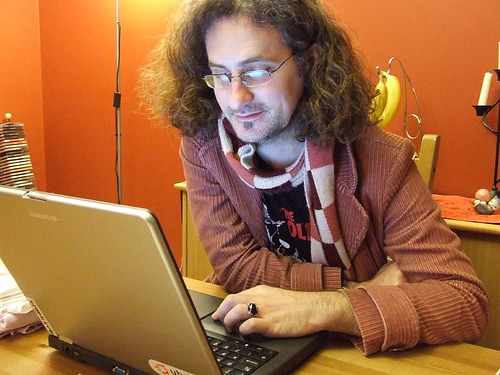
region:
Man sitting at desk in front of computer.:
[136, 1, 489, 356]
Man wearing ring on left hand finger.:
[243, 294, 265, 319]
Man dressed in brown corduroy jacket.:
[176, 119, 491, 360]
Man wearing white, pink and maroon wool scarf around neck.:
[218, 115, 355, 280]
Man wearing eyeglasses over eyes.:
[193, 50, 298, 92]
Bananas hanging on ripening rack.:
[367, 53, 429, 140]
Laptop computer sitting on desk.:
[1, 181, 321, 371]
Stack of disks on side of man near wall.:
[0, 112, 38, 188]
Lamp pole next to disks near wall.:
[100, 0, 130, 200]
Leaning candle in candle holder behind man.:
[469, 62, 499, 118]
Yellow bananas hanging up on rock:
[361, 58, 406, 139]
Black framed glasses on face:
[193, 58, 317, 102]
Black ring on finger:
[241, 296, 266, 328]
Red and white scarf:
[208, 124, 345, 279]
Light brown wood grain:
[480, 345, 499, 364]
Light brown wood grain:
[449, 344, 473, 368]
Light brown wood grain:
[419, 342, 438, 372]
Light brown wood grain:
[366, 349, 383, 370]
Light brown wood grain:
[323, 350, 331, 365]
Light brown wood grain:
[14, 342, 64, 374]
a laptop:
[1, 190, 188, 343]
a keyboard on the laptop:
[206, 338, 257, 360]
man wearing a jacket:
[373, 181, 429, 268]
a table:
[322, 355, 353, 374]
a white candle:
[477, 69, 493, 106]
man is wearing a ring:
[237, 303, 264, 313]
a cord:
[110, 73, 122, 179]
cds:
[5, 127, 30, 183]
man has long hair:
[306, 25, 348, 88]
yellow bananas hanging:
[376, 65, 398, 107]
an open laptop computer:
[0, 185, 325, 372]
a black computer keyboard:
[200, 332, 277, 374]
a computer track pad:
[201, 310, 233, 322]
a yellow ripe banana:
[377, 67, 399, 124]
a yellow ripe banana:
[369, 69, 386, 117]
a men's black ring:
[247, 300, 258, 318]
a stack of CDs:
[0, 121, 36, 191]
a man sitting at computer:
[1, 0, 488, 373]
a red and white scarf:
[211, 108, 351, 270]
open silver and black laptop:
[0, 178, 326, 373]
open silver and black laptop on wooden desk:
[1, 181, 496, 373]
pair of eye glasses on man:
[192, 52, 312, 92]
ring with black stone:
[245, 298, 259, 318]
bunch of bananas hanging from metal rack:
[363, 54, 442, 195]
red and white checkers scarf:
[214, 118, 356, 292]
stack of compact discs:
[1, 115, 41, 194]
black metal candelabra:
[472, 37, 499, 193]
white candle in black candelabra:
[468, 60, 496, 119]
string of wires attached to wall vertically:
[108, 28, 135, 202]